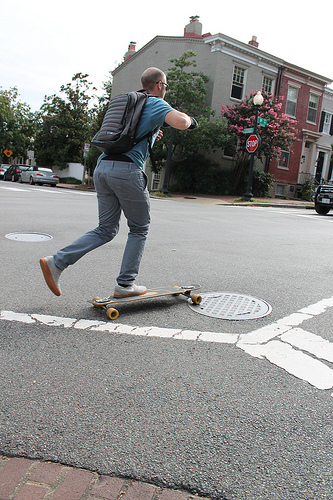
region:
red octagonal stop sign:
[240, 133, 261, 155]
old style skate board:
[79, 282, 204, 329]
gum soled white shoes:
[36, 255, 65, 300]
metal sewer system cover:
[187, 281, 272, 334]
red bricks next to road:
[0, 445, 206, 499]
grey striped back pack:
[87, 83, 147, 165]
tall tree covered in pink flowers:
[220, 86, 300, 199]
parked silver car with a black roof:
[17, 163, 62, 192]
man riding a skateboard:
[22, 63, 202, 323]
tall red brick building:
[267, 56, 321, 204]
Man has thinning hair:
[131, 63, 177, 102]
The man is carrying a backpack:
[89, 83, 151, 161]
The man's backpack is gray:
[87, 80, 160, 162]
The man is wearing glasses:
[151, 77, 175, 95]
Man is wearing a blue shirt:
[106, 88, 170, 174]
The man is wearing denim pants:
[36, 153, 191, 290]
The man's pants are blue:
[47, 149, 161, 305]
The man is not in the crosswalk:
[53, 48, 331, 394]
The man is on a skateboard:
[39, 215, 225, 346]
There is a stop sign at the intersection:
[227, 117, 269, 229]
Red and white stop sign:
[245, 135, 262, 154]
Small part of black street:
[245, 245, 271, 261]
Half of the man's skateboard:
[148, 282, 203, 316]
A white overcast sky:
[60, 33, 84, 51]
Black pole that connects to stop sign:
[244, 157, 257, 196]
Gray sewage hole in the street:
[2, 227, 58, 245]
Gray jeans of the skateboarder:
[97, 168, 149, 273]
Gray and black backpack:
[97, 88, 145, 153]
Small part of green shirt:
[151, 100, 158, 114]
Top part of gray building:
[209, 57, 222, 76]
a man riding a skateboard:
[35, 51, 214, 337]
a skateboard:
[92, 281, 210, 324]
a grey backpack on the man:
[82, 79, 155, 159]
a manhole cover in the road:
[187, 276, 272, 325]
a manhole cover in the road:
[5, 223, 53, 250]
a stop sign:
[239, 120, 265, 202]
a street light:
[235, 85, 277, 212]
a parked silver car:
[16, 162, 62, 183]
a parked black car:
[4, 162, 27, 183]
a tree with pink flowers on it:
[213, 90, 311, 187]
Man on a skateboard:
[35, 64, 216, 321]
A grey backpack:
[79, 86, 153, 163]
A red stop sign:
[240, 132, 267, 160]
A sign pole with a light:
[227, 83, 271, 203]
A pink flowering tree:
[218, 87, 303, 199]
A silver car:
[15, 164, 65, 188]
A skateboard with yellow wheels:
[76, 278, 217, 330]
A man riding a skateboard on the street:
[9, 19, 328, 402]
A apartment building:
[98, 5, 332, 205]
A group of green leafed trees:
[0, 65, 96, 172]